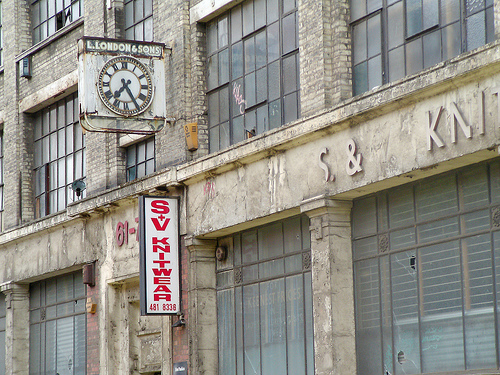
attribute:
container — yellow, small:
[183, 120, 199, 150]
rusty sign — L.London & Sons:
[77, 35, 169, 58]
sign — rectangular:
[135, 192, 194, 319]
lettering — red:
[149, 203, 172, 303]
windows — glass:
[21, 263, 106, 374]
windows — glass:
[205, 217, 320, 372]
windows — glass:
[337, 153, 499, 373]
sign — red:
[105, 218, 140, 248]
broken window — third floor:
[52, 6, 77, 32]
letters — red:
[158, 239, 166, 264]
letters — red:
[231, 80, 246, 118]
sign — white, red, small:
[138, 191, 183, 316]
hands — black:
[113, 77, 141, 107]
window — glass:
[355, 195, 381, 367]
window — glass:
[388, 178, 415, 365]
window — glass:
[422, 172, 458, 367]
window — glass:
[458, 169, 498, 361]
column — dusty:
[0, 275, 32, 373]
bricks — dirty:
[302, 22, 354, 92]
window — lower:
[382, 249, 419, 351]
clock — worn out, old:
[95, 51, 154, 117]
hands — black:
[118, 75, 151, 107]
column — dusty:
[295, 199, 356, 373]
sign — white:
[142, 199, 182, 315]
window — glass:
[207, 26, 219, 56]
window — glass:
[219, 20, 229, 47]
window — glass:
[215, 48, 233, 88]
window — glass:
[228, 43, 246, 79]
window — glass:
[242, 36, 258, 73]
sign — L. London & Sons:
[82, 34, 164, 57]